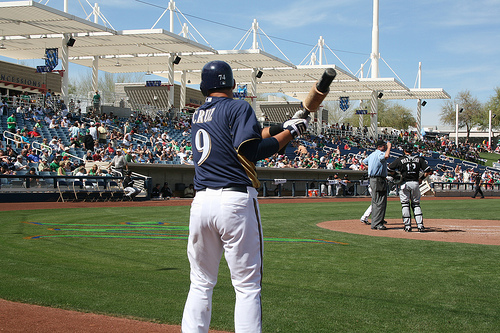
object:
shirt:
[192, 96, 263, 190]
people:
[0, 93, 500, 190]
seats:
[12, 102, 142, 159]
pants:
[179, 186, 263, 332]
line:
[245, 190, 268, 330]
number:
[218, 74, 225, 80]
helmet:
[200, 60, 236, 97]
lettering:
[189, 105, 220, 134]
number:
[195, 129, 212, 166]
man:
[363, 135, 401, 235]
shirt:
[363, 149, 388, 178]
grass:
[44, 189, 157, 279]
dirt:
[139, 218, 500, 332]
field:
[0, 196, 499, 333]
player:
[180, 60, 312, 333]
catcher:
[387, 143, 432, 232]